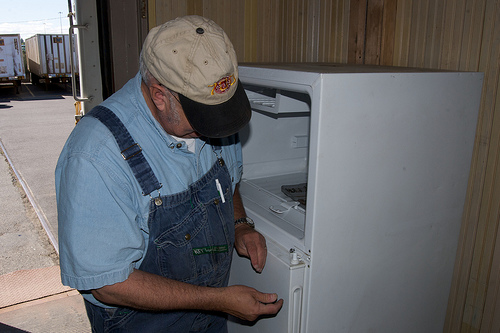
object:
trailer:
[23, 32, 78, 90]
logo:
[209, 75, 236, 96]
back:
[37, 36, 74, 76]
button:
[154, 198, 163, 206]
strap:
[82, 106, 166, 209]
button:
[219, 158, 225, 167]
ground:
[6, 167, 54, 252]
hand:
[208, 283, 284, 323]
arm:
[60, 159, 222, 312]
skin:
[91, 267, 219, 313]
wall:
[144, 1, 496, 331]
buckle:
[142, 180, 164, 206]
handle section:
[285, 286, 303, 333]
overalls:
[72, 102, 235, 333]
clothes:
[57, 70, 244, 333]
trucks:
[0, 35, 26, 87]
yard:
[2, 91, 65, 333]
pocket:
[214, 186, 236, 253]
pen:
[214, 177, 226, 204]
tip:
[195, 27, 206, 35]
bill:
[179, 78, 253, 141]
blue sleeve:
[53, 71, 239, 291]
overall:
[51, 103, 234, 331]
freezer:
[210, 61, 485, 333]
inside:
[241, 102, 311, 211]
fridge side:
[314, 67, 490, 331]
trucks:
[21, 33, 73, 89]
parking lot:
[0, 25, 66, 287]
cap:
[140, 17, 252, 138]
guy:
[51, 16, 280, 333]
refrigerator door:
[223, 228, 301, 333]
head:
[139, 15, 257, 141]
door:
[226, 70, 314, 327]